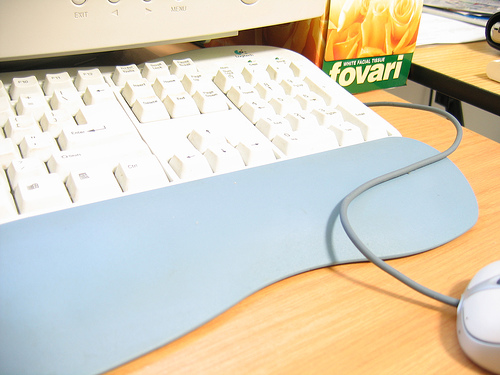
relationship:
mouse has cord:
[458, 261, 500, 373] [339, 101, 463, 306]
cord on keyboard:
[339, 101, 463, 306] [3, 43, 404, 227]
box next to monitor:
[205, 2, 425, 96] [2, 0, 328, 61]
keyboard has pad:
[3, 43, 404, 227] [1, 136, 481, 374]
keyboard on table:
[3, 43, 404, 227] [98, 43, 498, 373]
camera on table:
[486, 7, 500, 85] [408, 39, 499, 117]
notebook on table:
[422, 1, 500, 26] [408, 39, 499, 117]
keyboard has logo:
[3, 43, 404, 227] [233, 48, 252, 59]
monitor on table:
[2, 0, 328, 61] [98, 43, 498, 373]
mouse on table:
[458, 261, 500, 373] [98, 43, 498, 373]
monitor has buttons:
[2, 0, 328, 61] [71, 0, 261, 8]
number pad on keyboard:
[214, 59, 388, 155] [3, 43, 404, 227]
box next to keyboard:
[205, 2, 425, 96] [3, 43, 404, 227]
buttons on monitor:
[71, 0, 261, 8] [2, 0, 328, 61]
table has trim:
[408, 39, 499, 117] [408, 59, 500, 120]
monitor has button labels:
[2, 0, 328, 61] [67, 3, 189, 22]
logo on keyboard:
[233, 48, 252, 59] [3, 43, 404, 227]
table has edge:
[408, 39, 499, 117] [408, 59, 500, 120]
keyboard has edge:
[3, 43, 404, 227] [297, 50, 402, 138]